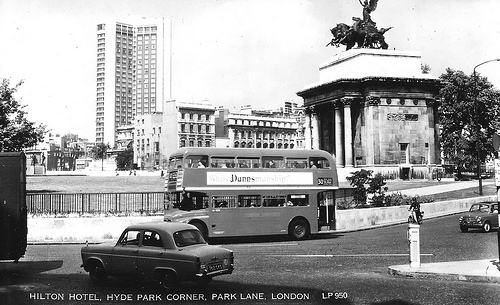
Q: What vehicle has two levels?
A: A bus.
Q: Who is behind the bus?
A: A biker.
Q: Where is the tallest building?
A: In the distance.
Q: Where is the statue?
A: On top of the building.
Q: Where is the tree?
A: Next to the street.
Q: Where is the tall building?
A: Behind the other buildings.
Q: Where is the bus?
A: On the road.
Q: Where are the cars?
A: On the road.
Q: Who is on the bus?
A: Passengers.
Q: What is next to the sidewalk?
A: A metal fence.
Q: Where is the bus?
A: On the corner.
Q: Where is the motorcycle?
A: Behind the bus.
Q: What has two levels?
A: A bus.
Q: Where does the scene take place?
A: Near a city street.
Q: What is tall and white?
A: Building.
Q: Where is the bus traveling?
A: In traffic.